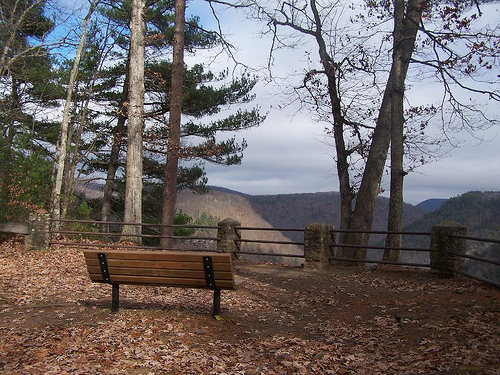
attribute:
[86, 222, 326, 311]
point — view, vantage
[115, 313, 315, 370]
leaves — fallen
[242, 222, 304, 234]
railings — three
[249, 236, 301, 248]
railings — three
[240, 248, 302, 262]
railings — three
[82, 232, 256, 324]
bench — visitors, convenience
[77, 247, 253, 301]
bench — wooden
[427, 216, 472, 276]
stone rock — gray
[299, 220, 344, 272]
stone rock — gray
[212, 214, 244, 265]
stone rock — gray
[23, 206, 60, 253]
stone rock — gray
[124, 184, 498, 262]
hills — background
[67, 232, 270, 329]
bench — visitors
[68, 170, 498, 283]
mountain — trees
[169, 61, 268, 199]
branches — fir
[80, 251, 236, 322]
bench — wooden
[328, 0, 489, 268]
trees — leafless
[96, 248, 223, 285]
plates — metal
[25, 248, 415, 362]
area — leafy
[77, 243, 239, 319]
bench — empty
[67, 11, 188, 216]
trees — green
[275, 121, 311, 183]
sky — cloudy, blue